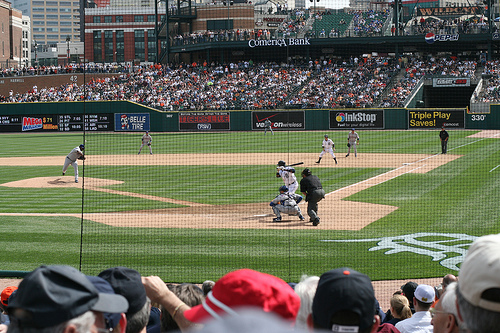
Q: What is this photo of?
A: A game.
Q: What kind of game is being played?
A: Baseball.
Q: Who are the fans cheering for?
A: Their team.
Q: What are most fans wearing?
A: Baseball hats.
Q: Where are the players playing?
A: On the field.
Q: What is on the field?
A: Dirt.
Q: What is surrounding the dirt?
A: Grass.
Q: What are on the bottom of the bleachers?
A: Posters.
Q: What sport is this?
A: Baseball.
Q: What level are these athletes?
A: Professional.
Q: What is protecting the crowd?
A: A net.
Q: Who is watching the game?
A: Fans.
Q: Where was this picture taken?
A: At a baseball stadium.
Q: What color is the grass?
A: Green.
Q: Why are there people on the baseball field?
A: To play baseball.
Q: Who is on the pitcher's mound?
A: A pitcher.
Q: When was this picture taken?
A: During the day.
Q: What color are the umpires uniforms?
A: Black.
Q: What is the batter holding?
A: A bat.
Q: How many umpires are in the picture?
A: Two.